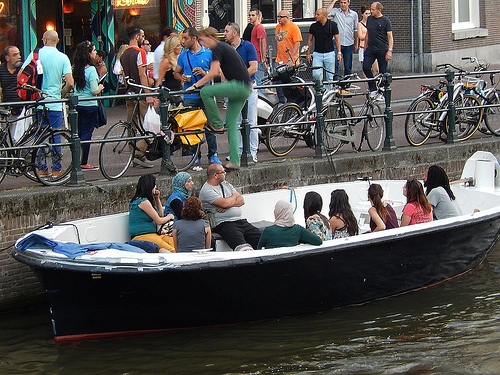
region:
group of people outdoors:
[36, 40, 463, 247]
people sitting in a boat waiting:
[5, 179, 479, 316]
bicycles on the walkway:
[328, 53, 498, 150]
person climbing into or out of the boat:
[163, 19, 260, 173]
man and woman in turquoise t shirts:
[10, 11, 112, 121]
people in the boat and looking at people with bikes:
[121, 174, 451, 239]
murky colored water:
[210, 282, 478, 352]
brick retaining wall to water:
[8, 136, 50, 311]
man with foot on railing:
[147, 73, 334, 158]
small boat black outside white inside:
[30, 261, 486, 348]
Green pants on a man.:
[197, 78, 253, 163]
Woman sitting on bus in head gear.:
[165, 170, 200, 222]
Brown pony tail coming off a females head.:
[367, 181, 391, 221]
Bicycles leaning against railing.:
[406, 55, 498, 145]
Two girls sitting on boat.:
[304, 188, 361, 245]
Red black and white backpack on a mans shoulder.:
[18, 47, 43, 100]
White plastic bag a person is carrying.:
[145, 102, 160, 139]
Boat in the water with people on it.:
[12, 150, 498, 341]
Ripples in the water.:
[360, 310, 445, 342]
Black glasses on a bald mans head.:
[277, 14, 292, 21]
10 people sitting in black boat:
[32, 125, 498, 350]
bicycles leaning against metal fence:
[12, 58, 488, 197]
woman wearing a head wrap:
[260, 193, 314, 252]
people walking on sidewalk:
[235, 0, 407, 85]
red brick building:
[390, 1, 483, 81]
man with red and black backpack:
[7, 18, 87, 108]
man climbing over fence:
[182, 24, 259, 170]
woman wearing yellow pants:
[127, 168, 173, 264]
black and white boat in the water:
[30, 158, 494, 349]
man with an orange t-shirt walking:
[269, 0, 310, 94]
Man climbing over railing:
[195, 25, 253, 172]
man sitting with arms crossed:
[198, 162, 260, 251]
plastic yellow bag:
[171, 106, 206, 143]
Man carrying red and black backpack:
[16, 26, 76, 178]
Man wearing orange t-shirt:
[273, 7, 303, 67]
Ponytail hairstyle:
[365, 182, 390, 222]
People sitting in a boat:
[6, 149, 498, 341]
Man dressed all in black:
[360, 0, 395, 90]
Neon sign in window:
[107, 0, 157, 12]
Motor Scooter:
[241, 57, 322, 150]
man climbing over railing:
[180, 22, 251, 168]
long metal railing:
[0, 67, 495, 187]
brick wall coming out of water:
[0, 137, 497, 302]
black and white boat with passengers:
[10, 147, 495, 342]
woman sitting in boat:
[125, 172, 170, 247]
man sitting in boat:
[196, 162, 257, 242]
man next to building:
[270, 10, 300, 67]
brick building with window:
[347, 0, 497, 70]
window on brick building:
[450, 0, 486, 36]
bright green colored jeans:
[195, 80, 250, 165]